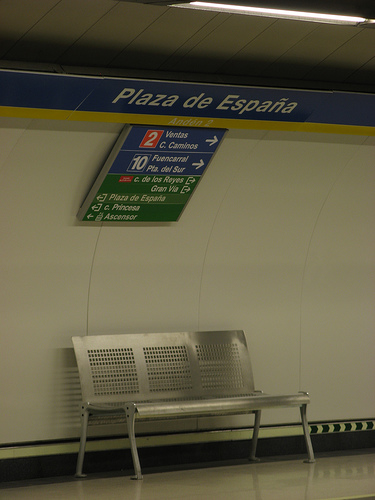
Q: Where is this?
A: This is at the station.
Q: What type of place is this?
A: It is a station.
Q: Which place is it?
A: It is a station.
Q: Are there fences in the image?
A: No, there are no fences.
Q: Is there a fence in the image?
A: No, there are no fences.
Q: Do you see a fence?
A: No, there are no fences.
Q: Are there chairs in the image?
A: No, there are no chairs.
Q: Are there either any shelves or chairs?
A: No, there are no chairs or shelves.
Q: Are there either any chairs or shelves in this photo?
A: No, there are no chairs or shelves.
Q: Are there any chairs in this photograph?
A: No, there are no chairs.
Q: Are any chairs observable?
A: No, there are no chairs.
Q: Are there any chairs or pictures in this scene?
A: No, there are no chairs or pictures.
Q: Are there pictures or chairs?
A: No, there are no chairs or pictures.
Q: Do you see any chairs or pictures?
A: No, there are no chairs or pictures.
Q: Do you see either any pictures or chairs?
A: No, there are no chairs or pictures.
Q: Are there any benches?
A: Yes, there is a bench.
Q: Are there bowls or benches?
A: Yes, there is a bench.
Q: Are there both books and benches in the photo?
A: No, there is a bench but no books.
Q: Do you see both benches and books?
A: No, there is a bench but no books.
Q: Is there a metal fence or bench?
A: Yes, there is a metal bench.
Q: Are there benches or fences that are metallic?
A: Yes, the bench is metallic.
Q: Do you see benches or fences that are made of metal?
A: Yes, the bench is made of metal.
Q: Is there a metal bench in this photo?
A: Yes, there is a metal bench.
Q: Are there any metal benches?
A: Yes, there is a metal bench.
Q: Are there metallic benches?
A: Yes, there is a metal bench.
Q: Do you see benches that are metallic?
A: Yes, there is a bench that is metallic.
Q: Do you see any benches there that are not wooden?
A: Yes, there is a metallic bench.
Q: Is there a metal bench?
A: Yes, there is a bench that is made of metal.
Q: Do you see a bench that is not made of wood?
A: Yes, there is a bench that is made of metal.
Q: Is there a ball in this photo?
A: No, there are no balls.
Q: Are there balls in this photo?
A: No, there are no balls.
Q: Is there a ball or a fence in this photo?
A: No, there are no balls or fences.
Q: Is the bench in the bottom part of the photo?
A: Yes, the bench is in the bottom of the image.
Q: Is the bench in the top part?
A: No, the bench is in the bottom of the image.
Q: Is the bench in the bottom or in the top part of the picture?
A: The bench is in the bottom of the image.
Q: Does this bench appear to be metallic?
A: Yes, the bench is metallic.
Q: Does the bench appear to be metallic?
A: Yes, the bench is metallic.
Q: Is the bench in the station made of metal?
A: Yes, the bench is made of metal.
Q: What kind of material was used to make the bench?
A: The bench is made of metal.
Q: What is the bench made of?
A: The bench is made of metal.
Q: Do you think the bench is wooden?
A: No, the bench is metallic.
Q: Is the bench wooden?
A: No, the bench is metallic.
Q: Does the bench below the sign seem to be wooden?
A: No, the bench is metallic.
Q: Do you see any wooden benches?
A: No, there is a bench but it is metallic.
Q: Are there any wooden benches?
A: No, there is a bench but it is metallic.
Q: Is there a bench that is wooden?
A: No, there is a bench but it is metallic.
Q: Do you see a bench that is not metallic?
A: No, there is a bench but it is metallic.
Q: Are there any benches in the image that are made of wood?
A: No, there is a bench but it is made of metal.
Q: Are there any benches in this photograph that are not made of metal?
A: No, there is a bench but it is made of metal.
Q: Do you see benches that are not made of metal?
A: No, there is a bench but it is made of metal.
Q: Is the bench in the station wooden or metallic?
A: The bench is metallic.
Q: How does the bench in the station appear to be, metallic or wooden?
A: The bench is metallic.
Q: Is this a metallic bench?
A: Yes, this is a metallic bench.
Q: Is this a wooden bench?
A: No, this is a metallic bench.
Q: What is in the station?
A: The bench is in the station.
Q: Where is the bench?
A: The bench is in the station.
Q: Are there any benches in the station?
A: Yes, there is a bench in the station.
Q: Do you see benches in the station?
A: Yes, there is a bench in the station.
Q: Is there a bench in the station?
A: Yes, there is a bench in the station.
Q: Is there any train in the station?
A: No, there is a bench in the station.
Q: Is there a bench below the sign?
A: Yes, there is a bench below the sign.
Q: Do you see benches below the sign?
A: Yes, there is a bench below the sign.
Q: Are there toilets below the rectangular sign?
A: No, there is a bench below the sign.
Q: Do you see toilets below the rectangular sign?
A: No, there is a bench below the sign.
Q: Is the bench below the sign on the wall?
A: Yes, the bench is below the sign.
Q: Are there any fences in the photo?
A: No, there are no fences.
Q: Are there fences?
A: No, there are no fences.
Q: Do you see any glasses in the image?
A: No, there are no glasses.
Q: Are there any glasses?
A: No, there are no glasses.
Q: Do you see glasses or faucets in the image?
A: No, there are no glasses or faucets.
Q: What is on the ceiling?
A: The light fixture is on the ceiling.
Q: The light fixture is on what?
A: The light fixture is on the ceiling.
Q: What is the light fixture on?
A: The light fixture is on the ceiling.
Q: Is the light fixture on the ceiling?
A: Yes, the light fixture is on the ceiling.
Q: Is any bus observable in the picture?
A: No, there are no buses.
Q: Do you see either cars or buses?
A: No, there are no buses or cars.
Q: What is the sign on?
A: The sign is on the wall.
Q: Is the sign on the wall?
A: Yes, the sign is on the wall.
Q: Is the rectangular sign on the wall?
A: Yes, the sign is on the wall.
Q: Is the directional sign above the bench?
A: Yes, the sign is above the bench.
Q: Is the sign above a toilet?
A: No, the sign is above the bench.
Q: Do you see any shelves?
A: No, there are no shelves.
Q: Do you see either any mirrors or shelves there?
A: No, there are no shelves or mirrors.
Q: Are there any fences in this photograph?
A: No, there are no fences.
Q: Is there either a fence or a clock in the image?
A: No, there are no fences or clocks.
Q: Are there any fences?
A: No, there are no fences.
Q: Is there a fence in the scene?
A: No, there are no fences.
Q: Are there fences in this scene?
A: No, there are no fences.